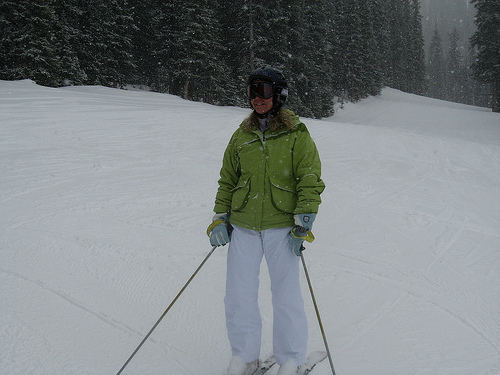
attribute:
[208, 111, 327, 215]
coat — green, padded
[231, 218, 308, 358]
pants — white, padded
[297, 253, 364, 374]
ski pole — tall, long, metal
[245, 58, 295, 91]
helmet — black, blue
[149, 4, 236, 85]
trees — pine, growing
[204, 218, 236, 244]
glove — blue, gray, white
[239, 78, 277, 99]
goggles — black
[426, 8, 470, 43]
snow — falling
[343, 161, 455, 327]
snow — white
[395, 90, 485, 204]
slope — snowy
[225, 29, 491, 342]
mountain — wintery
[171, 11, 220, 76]
tree — snow covered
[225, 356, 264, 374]
boots — white